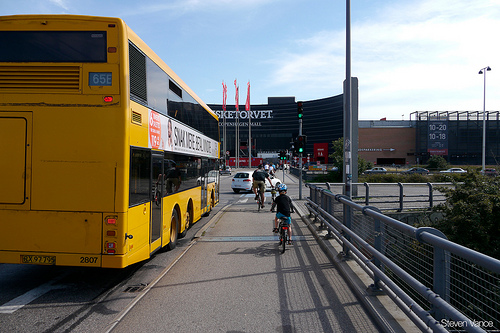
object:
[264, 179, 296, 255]
people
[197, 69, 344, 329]
outdoors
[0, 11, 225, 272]
bus